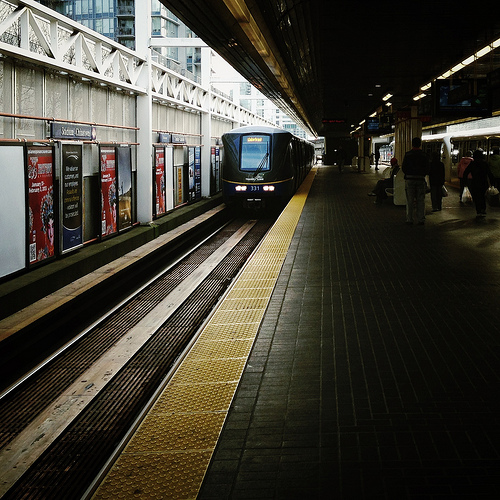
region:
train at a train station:
[208, 118, 320, 218]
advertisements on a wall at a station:
[12, 125, 227, 267]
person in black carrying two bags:
[459, 146, 499, 224]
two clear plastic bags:
[458, 185, 498, 208]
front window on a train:
[239, 133, 270, 176]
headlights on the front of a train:
[230, 180, 277, 193]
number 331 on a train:
[248, 183, 260, 193]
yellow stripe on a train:
[218, 175, 291, 185]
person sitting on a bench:
[364, 155, 401, 212]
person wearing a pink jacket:
[453, 147, 478, 209]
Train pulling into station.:
[165, 85, 402, 303]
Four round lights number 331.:
[214, 123, 296, 221]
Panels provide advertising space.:
[17, 127, 211, 254]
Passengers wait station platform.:
[372, 138, 499, 225]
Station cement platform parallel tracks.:
[276, 163, 353, 419]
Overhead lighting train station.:
[407, 35, 496, 104]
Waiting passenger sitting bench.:
[361, 156, 404, 208]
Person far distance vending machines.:
[372, 138, 392, 171]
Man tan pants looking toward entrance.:
[401, 131, 431, 231]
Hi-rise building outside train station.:
[62, 1, 216, 104]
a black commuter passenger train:
[219, 124, 318, 209]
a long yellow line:
[94, 162, 316, 497]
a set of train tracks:
[0, 206, 275, 498]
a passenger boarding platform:
[91, 160, 498, 497]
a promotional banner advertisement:
[25, 143, 57, 268]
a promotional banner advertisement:
[56, 143, 84, 253]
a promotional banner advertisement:
[95, 143, 117, 241]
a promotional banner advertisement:
[115, 142, 137, 232]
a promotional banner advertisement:
[151, 141, 166, 218]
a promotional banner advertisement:
[184, 145, 196, 201]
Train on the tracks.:
[208, 85, 324, 235]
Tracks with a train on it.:
[171, 182, 285, 289]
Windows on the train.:
[201, 79, 283, 254]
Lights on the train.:
[225, 171, 306, 217]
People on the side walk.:
[369, 109, 460, 237]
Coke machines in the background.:
[27, 117, 215, 279]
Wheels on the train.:
[223, 191, 282, 227]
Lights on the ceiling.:
[353, 53, 490, 129]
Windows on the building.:
[115, 12, 174, 55]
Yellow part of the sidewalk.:
[191, 334, 279, 430]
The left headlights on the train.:
[227, 181, 247, 196]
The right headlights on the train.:
[265, 185, 270, 192]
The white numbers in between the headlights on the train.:
[248, 180, 264, 197]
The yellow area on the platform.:
[125, 155, 300, 491]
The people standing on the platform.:
[371, 134, 494, 222]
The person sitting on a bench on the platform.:
[373, 151, 395, 200]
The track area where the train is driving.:
[11, 182, 247, 423]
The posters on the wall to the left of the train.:
[24, 137, 210, 270]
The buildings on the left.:
[78, 4, 308, 139]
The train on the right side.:
[405, 123, 498, 173]